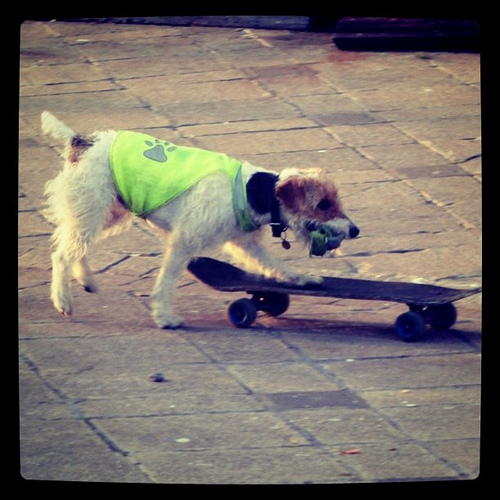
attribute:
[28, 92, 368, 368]
dog — small, white, furry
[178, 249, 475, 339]
skateboard — black, long, small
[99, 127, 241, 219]
vest — small, green, cloth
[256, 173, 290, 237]
collar — long, black, metal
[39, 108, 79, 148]
tail — short, white, furry, canine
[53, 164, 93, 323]
leg — short, fluffy, white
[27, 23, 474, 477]
area — large, open, stone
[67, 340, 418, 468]
brick — stone, small, square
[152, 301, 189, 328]
paw — small, white, furry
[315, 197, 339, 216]
eye — round, small, black